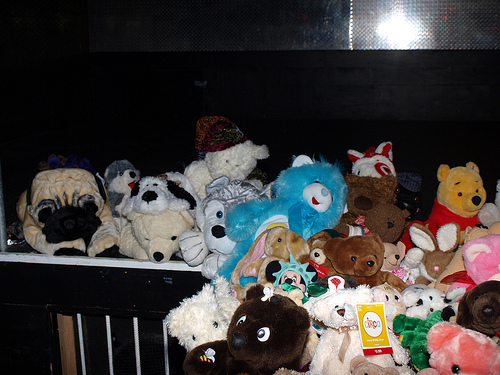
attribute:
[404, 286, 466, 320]
stuffed animal — fluffy, white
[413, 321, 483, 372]
bear — pink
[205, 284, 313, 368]
bear — dark, brown, teddy